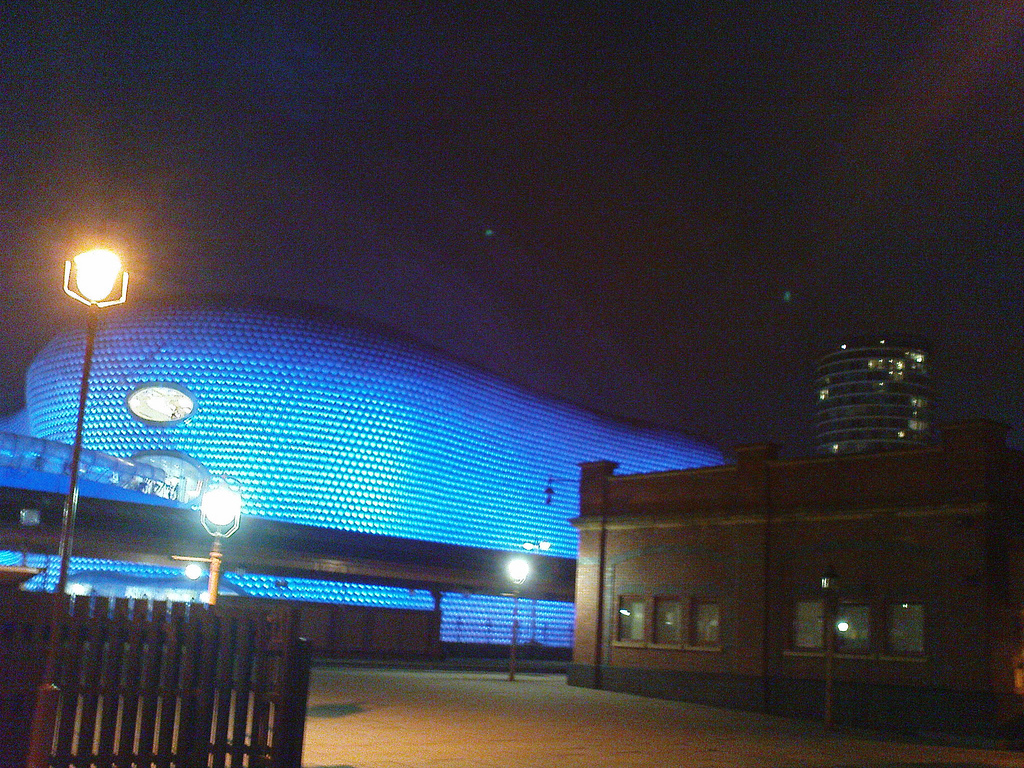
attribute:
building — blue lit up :
[4, 301, 715, 671]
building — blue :
[516, 404, 981, 722]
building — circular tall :
[555, 402, 992, 727]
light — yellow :
[51, 230, 142, 304]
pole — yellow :
[43, 314, 111, 595]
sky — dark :
[226, 57, 570, 120]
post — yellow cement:
[200, 545, 229, 598]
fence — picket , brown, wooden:
[4, 575, 318, 761]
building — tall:
[807, 332, 939, 462]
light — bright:
[199, 486, 245, 528]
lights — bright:
[63, 231, 249, 534]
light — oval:
[128, 378, 198, 422]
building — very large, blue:
[1, 287, 738, 638]